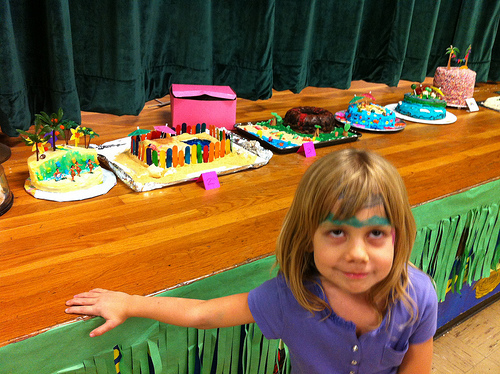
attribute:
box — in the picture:
[172, 85, 236, 132]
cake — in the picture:
[23, 139, 117, 204]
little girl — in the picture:
[65, 149, 435, 371]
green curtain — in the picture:
[2, 1, 499, 135]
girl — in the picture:
[63, 151, 439, 372]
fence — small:
[132, 121, 232, 166]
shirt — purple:
[239, 255, 437, 370]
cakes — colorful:
[438, 41, 478, 106]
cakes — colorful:
[388, 82, 458, 123]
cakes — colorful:
[336, 90, 410, 130]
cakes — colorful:
[235, 106, 363, 148]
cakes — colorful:
[98, 124, 270, 195]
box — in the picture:
[161, 77, 242, 137]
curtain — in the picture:
[13, 0, 492, 93]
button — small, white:
[351, 358, 358, 366]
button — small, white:
[351, 345, 359, 352]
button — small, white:
[348, 370, 357, 372]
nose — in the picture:
[344, 237, 374, 266]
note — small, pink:
[198, 170, 222, 190]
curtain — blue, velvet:
[0, 0, 497, 137]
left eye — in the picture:
[364, 222, 396, 244]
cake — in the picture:
[279, 100, 339, 135]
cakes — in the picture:
[241, 40, 483, 165]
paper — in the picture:
[18, 231, 499, 372]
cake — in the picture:
[35, 105, 129, 192]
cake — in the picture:
[282, 107, 337, 136]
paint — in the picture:
[318, 193, 387, 230]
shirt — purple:
[237, 263, 438, 366]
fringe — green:
[8, 170, 498, 371]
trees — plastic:
[21, 104, 79, 151]